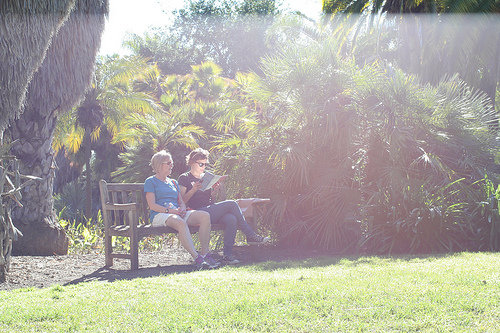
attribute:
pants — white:
[150, 207, 193, 227]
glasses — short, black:
[191, 160, 208, 169]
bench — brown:
[98, 180, 233, 274]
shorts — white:
[152, 208, 209, 229]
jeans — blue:
[200, 200, 260, 257]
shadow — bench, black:
[18, 229, 260, 286]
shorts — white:
[154, 210, 194, 226]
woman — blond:
[147, 150, 212, 265]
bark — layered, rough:
[34, 47, 90, 209]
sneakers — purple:
[195, 252, 222, 270]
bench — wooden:
[94, 172, 240, 273]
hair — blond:
[149, 150, 174, 175]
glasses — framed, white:
[161, 159, 171, 166]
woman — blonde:
[142, 149, 218, 271]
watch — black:
[162, 205, 172, 214]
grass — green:
[25, 240, 497, 330]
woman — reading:
[182, 138, 269, 268]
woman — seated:
[177, 146, 266, 266]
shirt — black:
[179, 170, 210, 209]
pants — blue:
[199, 200, 254, 255]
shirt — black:
[179, 170, 216, 208]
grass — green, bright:
[4, 252, 497, 331]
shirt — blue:
[143, 180, 192, 214]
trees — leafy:
[98, 0, 495, 251]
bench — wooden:
[104, 167, 252, 234]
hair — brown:
[184, 146, 209, 176]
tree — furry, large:
[15, 4, 116, 257]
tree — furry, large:
[0, 1, 76, 271]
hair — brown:
[187, 149, 207, 164]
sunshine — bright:
[35, 6, 457, 190]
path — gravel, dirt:
[3, 252, 227, 282]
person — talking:
[182, 144, 268, 267]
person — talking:
[180, 145, 271, 255]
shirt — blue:
[143, 170, 189, 222]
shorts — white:
[150, 209, 197, 224]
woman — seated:
[175, 148, 273, 268]